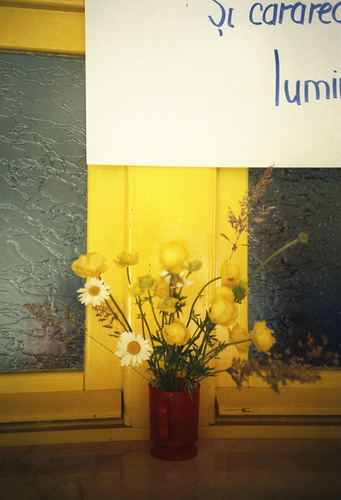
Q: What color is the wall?
A: Yellow.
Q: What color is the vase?
A: Red.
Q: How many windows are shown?
A: Two.